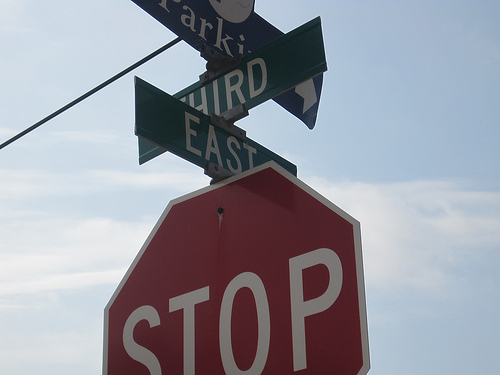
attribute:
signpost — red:
[101, 159, 370, 373]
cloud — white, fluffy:
[382, 184, 449, 244]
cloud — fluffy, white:
[68, 222, 118, 260]